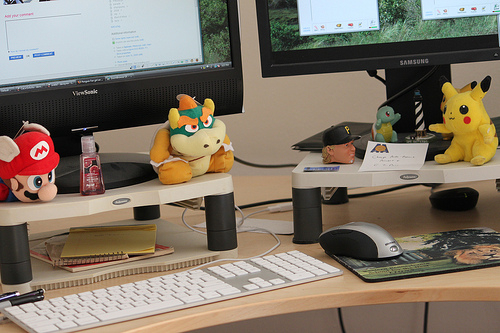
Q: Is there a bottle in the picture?
A: Yes, there is a bottle.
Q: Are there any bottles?
A: Yes, there is a bottle.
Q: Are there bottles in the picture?
A: Yes, there is a bottle.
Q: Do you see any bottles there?
A: Yes, there is a bottle.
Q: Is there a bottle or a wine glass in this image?
A: Yes, there is a bottle.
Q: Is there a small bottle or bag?
A: Yes, there is a small bottle.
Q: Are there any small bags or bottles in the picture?
A: Yes, there is a small bottle.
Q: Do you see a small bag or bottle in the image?
A: Yes, there is a small bottle.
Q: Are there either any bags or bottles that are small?
A: Yes, the bottle is small.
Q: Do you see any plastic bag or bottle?
A: Yes, there is a plastic bottle.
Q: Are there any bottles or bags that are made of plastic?
A: Yes, the bottle is made of plastic.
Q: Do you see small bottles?
A: Yes, there is a small bottle.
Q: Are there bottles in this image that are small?
A: Yes, there is a bottle that is small.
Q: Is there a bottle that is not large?
A: Yes, there is a small bottle.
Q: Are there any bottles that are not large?
A: Yes, there is a small bottle.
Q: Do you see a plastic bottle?
A: Yes, there is a bottle that is made of plastic.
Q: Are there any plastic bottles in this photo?
A: Yes, there is a bottle that is made of plastic.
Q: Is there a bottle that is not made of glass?
A: Yes, there is a bottle that is made of plastic.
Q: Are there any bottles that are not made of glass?
A: Yes, there is a bottle that is made of plastic.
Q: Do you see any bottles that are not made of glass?
A: Yes, there is a bottle that is made of plastic.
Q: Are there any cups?
A: No, there are no cups.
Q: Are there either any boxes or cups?
A: No, there are no cups or boxes.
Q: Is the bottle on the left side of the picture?
A: Yes, the bottle is on the left of the image.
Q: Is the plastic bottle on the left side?
A: Yes, the bottle is on the left of the image.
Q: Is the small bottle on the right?
A: No, the bottle is on the left of the image.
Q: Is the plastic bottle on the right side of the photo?
A: No, the bottle is on the left of the image.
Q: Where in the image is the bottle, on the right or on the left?
A: The bottle is on the left of the image.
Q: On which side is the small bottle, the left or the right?
A: The bottle is on the left of the image.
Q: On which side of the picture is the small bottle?
A: The bottle is on the left of the image.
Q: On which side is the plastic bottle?
A: The bottle is on the left of the image.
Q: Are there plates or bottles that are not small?
A: No, there is a bottle but it is small.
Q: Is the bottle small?
A: Yes, the bottle is small.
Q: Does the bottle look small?
A: Yes, the bottle is small.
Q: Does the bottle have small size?
A: Yes, the bottle is small.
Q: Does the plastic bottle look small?
A: Yes, the bottle is small.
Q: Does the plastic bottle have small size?
A: Yes, the bottle is small.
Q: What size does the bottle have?
A: The bottle has small size.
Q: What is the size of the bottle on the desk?
A: The bottle is small.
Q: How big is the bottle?
A: The bottle is small.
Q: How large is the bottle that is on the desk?
A: The bottle is small.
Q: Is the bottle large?
A: No, the bottle is small.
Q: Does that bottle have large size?
A: No, the bottle is small.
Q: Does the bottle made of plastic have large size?
A: No, the bottle is small.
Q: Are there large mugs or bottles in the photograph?
A: No, there is a bottle but it is small.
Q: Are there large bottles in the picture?
A: No, there is a bottle but it is small.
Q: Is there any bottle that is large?
A: No, there is a bottle but it is small.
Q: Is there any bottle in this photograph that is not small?
A: No, there is a bottle but it is small.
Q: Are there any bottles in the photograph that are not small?
A: No, there is a bottle but it is small.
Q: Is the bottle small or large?
A: The bottle is small.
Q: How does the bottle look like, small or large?
A: The bottle is small.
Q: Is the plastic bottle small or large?
A: The bottle is small.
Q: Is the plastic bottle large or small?
A: The bottle is small.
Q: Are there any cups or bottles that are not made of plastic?
A: No, there is a bottle but it is made of plastic.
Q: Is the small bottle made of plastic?
A: Yes, the bottle is made of plastic.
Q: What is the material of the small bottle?
A: The bottle is made of plastic.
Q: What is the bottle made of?
A: The bottle is made of plastic.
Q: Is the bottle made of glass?
A: No, the bottle is made of plastic.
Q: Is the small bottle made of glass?
A: No, the bottle is made of plastic.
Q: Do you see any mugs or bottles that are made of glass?
A: No, there is a bottle but it is made of plastic.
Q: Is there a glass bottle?
A: No, there is a bottle but it is made of plastic.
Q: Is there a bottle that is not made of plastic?
A: No, there is a bottle but it is made of plastic.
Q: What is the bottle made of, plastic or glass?
A: The bottle is made of plastic.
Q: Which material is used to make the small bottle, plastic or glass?
A: The bottle is made of plastic.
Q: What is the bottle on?
A: The bottle is on the desk.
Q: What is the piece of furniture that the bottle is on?
A: The piece of furniture is a desk.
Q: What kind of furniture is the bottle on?
A: The bottle is on the desk.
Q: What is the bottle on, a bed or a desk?
A: The bottle is on a desk.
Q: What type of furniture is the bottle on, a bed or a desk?
A: The bottle is on a desk.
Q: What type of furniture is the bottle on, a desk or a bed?
A: The bottle is on a desk.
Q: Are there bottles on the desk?
A: Yes, there is a bottle on the desk.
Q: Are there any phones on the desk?
A: No, there is a bottle on the desk.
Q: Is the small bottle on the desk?
A: Yes, the bottle is on the desk.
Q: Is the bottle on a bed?
A: No, the bottle is on the desk.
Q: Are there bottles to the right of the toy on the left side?
A: Yes, there is a bottle to the right of the toy.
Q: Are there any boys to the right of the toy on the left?
A: No, there is a bottle to the right of the toy.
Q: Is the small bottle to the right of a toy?
A: Yes, the bottle is to the right of a toy.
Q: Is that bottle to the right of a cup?
A: No, the bottle is to the right of a toy.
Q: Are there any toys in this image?
A: Yes, there is a toy.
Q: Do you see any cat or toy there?
A: Yes, there is a toy.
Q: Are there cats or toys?
A: Yes, there is a toy.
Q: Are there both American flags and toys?
A: No, there is a toy but no American flags.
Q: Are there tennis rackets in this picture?
A: No, there are no tennis rackets.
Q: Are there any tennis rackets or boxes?
A: No, there are no tennis rackets or boxes.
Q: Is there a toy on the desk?
A: Yes, there is a toy on the desk.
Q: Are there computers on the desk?
A: No, there is a toy on the desk.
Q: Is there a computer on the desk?
A: No, there is a toy on the desk.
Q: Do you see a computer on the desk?
A: No, there is a toy on the desk.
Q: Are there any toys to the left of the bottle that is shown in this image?
A: Yes, there is a toy to the left of the bottle.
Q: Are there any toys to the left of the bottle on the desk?
A: Yes, there is a toy to the left of the bottle.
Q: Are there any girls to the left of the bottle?
A: No, there is a toy to the left of the bottle.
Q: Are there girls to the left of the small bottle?
A: No, there is a toy to the left of the bottle.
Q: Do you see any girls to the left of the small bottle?
A: No, there is a toy to the left of the bottle.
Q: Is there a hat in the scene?
A: Yes, there is a hat.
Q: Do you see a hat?
A: Yes, there is a hat.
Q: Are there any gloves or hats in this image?
A: Yes, there is a hat.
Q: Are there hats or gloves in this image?
A: Yes, there is a hat.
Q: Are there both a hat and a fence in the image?
A: No, there is a hat but no fences.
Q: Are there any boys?
A: No, there are no boys.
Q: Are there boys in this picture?
A: No, there are no boys.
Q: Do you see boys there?
A: No, there are no boys.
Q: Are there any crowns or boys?
A: No, there are no boys or crowns.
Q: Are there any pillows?
A: No, there are no pillows.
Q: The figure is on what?
A: The figure is on the desk.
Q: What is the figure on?
A: The figure is on the desk.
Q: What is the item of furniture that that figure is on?
A: The piece of furniture is a desk.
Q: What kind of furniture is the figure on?
A: The figure is on the desk.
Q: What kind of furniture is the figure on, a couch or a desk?
A: The figure is on a desk.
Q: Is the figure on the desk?
A: Yes, the figure is on the desk.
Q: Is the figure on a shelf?
A: No, the figure is on the desk.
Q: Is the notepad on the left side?
A: Yes, the notepad is on the left of the image.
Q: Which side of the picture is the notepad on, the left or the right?
A: The notepad is on the left of the image.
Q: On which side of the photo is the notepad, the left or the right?
A: The notepad is on the left of the image.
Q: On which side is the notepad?
A: The notepad is on the left of the image.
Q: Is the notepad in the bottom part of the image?
A: Yes, the notepad is in the bottom of the image.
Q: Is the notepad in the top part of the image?
A: No, the notepad is in the bottom of the image.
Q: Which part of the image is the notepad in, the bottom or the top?
A: The notepad is in the bottom of the image.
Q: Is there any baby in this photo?
A: No, there are no babies.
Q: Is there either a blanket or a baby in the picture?
A: No, there are no babies or blankets.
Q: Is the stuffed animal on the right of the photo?
A: Yes, the stuffed animal is on the right of the image.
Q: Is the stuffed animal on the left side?
A: No, the stuffed animal is on the right of the image.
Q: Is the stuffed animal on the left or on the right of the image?
A: The stuffed animal is on the right of the image.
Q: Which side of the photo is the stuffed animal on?
A: The stuffed animal is on the right of the image.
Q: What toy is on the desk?
A: The toy is a stuffed animal.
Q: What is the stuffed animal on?
A: The stuffed animal is on the desk.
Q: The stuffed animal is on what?
A: The stuffed animal is on the desk.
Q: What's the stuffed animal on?
A: The stuffed animal is on the desk.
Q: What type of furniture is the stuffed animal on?
A: The stuffed animal is on the desk.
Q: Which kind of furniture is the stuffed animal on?
A: The stuffed animal is on the desk.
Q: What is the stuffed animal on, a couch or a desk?
A: The stuffed animal is on a desk.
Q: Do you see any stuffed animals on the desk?
A: Yes, there is a stuffed animal on the desk.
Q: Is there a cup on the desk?
A: No, there is a stuffed animal on the desk.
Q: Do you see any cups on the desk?
A: No, there is a stuffed animal on the desk.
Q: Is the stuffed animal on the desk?
A: Yes, the stuffed animal is on the desk.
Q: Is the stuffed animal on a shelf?
A: No, the stuffed animal is on the desk.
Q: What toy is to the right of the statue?
A: The toy is a stuffed animal.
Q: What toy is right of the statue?
A: The toy is a stuffed animal.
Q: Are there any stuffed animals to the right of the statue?
A: Yes, there is a stuffed animal to the right of the statue.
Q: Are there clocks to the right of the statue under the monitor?
A: No, there is a stuffed animal to the right of the statue.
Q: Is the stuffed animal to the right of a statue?
A: Yes, the stuffed animal is to the right of a statue.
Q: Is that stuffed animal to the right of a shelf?
A: No, the stuffed animal is to the right of a statue.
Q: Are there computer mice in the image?
A: Yes, there is a computer mouse.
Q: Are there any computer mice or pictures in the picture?
A: Yes, there is a computer mouse.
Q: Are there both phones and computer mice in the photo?
A: No, there is a computer mouse but no phones.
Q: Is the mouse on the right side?
A: Yes, the mouse is on the right of the image.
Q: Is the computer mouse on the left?
A: No, the computer mouse is on the right of the image.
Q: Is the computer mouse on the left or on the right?
A: The computer mouse is on the right of the image.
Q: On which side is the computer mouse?
A: The computer mouse is on the right of the image.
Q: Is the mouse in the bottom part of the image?
A: Yes, the mouse is in the bottom of the image.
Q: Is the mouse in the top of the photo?
A: No, the mouse is in the bottom of the image.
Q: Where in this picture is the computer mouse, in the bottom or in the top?
A: The computer mouse is in the bottom of the image.